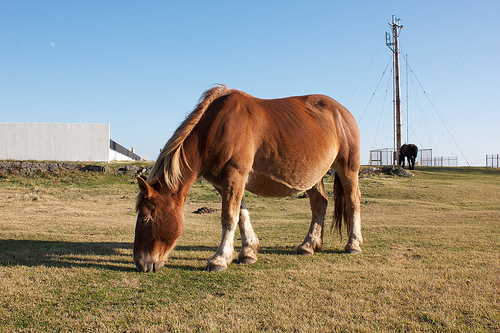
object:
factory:
[0, 119, 147, 162]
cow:
[393, 143, 418, 170]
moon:
[51, 42, 55, 47]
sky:
[116, 76, 175, 110]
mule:
[133, 82, 363, 273]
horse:
[133, 82, 361, 273]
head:
[133, 176, 185, 273]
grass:
[164, 269, 220, 295]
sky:
[114, 48, 173, 84]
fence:
[434, 156, 459, 167]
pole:
[379, 13, 401, 147]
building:
[0, 122, 146, 163]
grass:
[116, 273, 182, 302]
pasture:
[0, 157, 500, 333]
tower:
[384, 14, 402, 166]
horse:
[393, 144, 418, 171]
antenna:
[360, 14, 469, 170]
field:
[1, 166, 500, 333]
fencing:
[369, 147, 458, 166]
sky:
[196, 0, 355, 50]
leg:
[297, 180, 328, 256]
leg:
[212, 185, 259, 264]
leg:
[205, 172, 244, 272]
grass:
[16, 279, 102, 315]